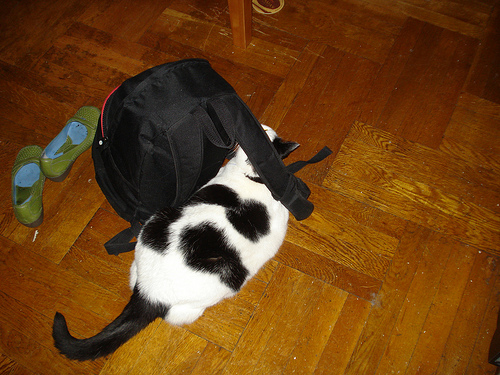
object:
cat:
[53, 116, 289, 357]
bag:
[91, 58, 333, 225]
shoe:
[10, 135, 45, 228]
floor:
[397, 73, 463, 161]